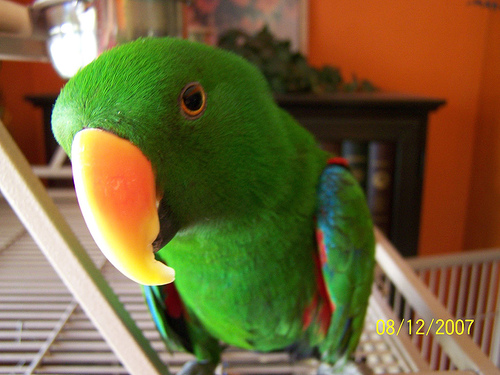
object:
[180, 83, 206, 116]
eye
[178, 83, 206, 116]
yellow circle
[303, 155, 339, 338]
vibrant coloring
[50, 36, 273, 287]
head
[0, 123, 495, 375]
bird cage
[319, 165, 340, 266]
blue patch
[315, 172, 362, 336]
feather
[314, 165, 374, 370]
wing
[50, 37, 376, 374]
bird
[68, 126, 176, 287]
beak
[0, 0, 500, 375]
wall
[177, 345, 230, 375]
feet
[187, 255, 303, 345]
stomach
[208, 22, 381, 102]
plant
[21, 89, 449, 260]
bookcase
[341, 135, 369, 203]
book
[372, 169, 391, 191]
symbol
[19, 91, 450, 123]
top shelf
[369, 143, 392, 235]
book